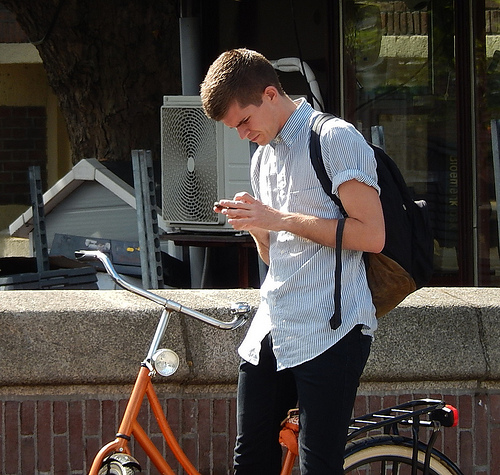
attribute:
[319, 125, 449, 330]
black bookbag — black 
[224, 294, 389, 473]
black pants — black 